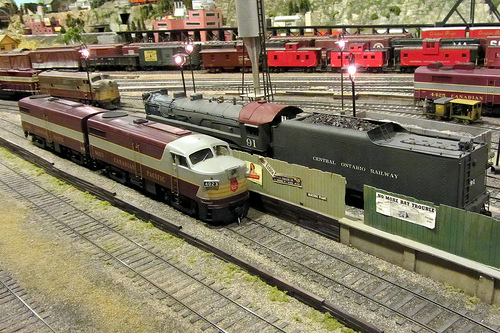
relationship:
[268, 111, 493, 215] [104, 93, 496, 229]
train car in track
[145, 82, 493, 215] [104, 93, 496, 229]
train car in track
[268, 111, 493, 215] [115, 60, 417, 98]
train car in track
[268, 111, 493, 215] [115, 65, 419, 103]
train car in track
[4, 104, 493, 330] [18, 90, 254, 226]
train in tracks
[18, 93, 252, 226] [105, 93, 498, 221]
train in tracks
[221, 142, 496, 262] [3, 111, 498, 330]
fence by tracks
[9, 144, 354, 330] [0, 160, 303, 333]
grass on tracks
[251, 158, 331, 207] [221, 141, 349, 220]
signs are on fence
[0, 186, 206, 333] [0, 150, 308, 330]
grass on train tracks